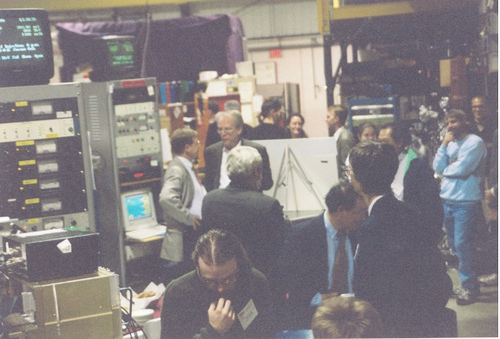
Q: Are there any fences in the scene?
A: No, there are no fences.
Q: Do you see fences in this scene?
A: No, there are no fences.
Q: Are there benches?
A: No, there are no benches.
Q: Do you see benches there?
A: No, there are no benches.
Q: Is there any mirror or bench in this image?
A: No, there are no benches or mirrors.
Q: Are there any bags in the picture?
A: No, there are no bags.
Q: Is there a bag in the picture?
A: No, there are no bags.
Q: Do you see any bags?
A: No, there are no bags.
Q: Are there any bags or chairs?
A: No, there are no bags or chairs.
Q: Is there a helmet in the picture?
A: No, there are no helmets.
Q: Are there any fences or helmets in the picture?
A: No, there are no helmets or fences.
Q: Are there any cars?
A: No, there are no cars.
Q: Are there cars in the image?
A: No, there are no cars.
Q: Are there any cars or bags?
A: No, there are no cars or bags.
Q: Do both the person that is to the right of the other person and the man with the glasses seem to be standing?
A: Yes, both the person and the man are standing.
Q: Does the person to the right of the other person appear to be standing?
A: Yes, the person is standing.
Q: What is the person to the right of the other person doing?
A: The person is standing.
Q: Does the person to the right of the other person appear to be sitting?
A: No, the person is standing.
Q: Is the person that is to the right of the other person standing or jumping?
A: The person is standing.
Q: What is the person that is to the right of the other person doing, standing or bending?
A: The person is standing.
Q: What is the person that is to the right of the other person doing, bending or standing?
A: The person is standing.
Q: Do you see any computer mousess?
A: No, there are no computer mousess.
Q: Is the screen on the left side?
A: Yes, the screen is on the left of the image.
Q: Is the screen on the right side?
A: No, the screen is on the left of the image.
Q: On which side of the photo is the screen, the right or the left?
A: The screen is on the left of the image.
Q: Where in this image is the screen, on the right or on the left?
A: The screen is on the left of the image.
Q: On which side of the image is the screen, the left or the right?
A: The screen is on the left of the image.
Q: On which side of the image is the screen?
A: The screen is on the left of the image.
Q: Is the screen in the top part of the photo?
A: Yes, the screen is in the top of the image.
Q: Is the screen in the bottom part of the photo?
A: No, the screen is in the top of the image.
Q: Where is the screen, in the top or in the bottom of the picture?
A: The screen is in the top of the image.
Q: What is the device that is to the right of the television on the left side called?
A: The device is a screen.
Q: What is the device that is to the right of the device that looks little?
A: The device is a screen.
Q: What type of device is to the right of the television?
A: The device is a screen.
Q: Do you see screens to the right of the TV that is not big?
A: Yes, there is a screen to the right of the television.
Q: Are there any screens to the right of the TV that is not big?
A: Yes, there is a screen to the right of the television.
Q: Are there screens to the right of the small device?
A: Yes, there is a screen to the right of the television.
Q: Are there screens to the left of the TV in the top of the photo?
A: No, the screen is to the right of the television.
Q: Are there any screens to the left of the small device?
A: No, the screen is to the right of the television.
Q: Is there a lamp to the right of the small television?
A: No, there is a screen to the right of the TV.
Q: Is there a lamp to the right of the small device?
A: No, there is a screen to the right of the TV.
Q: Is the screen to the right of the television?
A: Yes, the screen is to the right of the television.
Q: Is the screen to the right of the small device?
A: Yes, the screen is to the right of the television.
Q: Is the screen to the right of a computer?
A: No, the screen is to the right of the television.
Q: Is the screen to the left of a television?
A: No, the screen is to the right of a television.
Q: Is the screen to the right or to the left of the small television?
A: The screen is to the right of the television.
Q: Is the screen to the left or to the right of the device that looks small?
A: The screen is to the right of the television.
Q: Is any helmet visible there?
A: No, there are no helmets.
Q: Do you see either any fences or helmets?
A: No, there are no helmets or fences.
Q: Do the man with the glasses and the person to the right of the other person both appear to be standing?
A: Yes, both the man and the person are standing.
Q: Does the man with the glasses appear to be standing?
A: Yes, the man is standing.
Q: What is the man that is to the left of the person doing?
A: The man is standing.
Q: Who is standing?
A: The man is standing.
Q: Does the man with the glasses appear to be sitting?
A: No, the man is standing.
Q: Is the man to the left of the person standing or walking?
A: The man is standing.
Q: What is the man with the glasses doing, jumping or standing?
A: The man is standing.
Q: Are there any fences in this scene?
A: No, there are no fences.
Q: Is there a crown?
A: No, there are no crowns.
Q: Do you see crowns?
A: No, there are no crowns.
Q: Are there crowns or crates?
A: No, there are no crowns or crates.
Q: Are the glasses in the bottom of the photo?
A: Yes, the glasses are in the bottom of the image.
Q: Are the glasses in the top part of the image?
A: No, the glasses are in the bottom of the image.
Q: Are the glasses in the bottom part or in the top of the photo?
A: The glasses are in the bottom of the image.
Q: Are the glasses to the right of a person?
A: No, the glasses are to the left of a person.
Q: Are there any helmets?
A: No, there are no helmets.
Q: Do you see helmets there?
A: No, there are no helmets.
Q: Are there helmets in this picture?
A: No, there are no helmets.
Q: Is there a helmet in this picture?
A: No, there are no helmets.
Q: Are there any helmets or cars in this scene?
A: No, there are no helmets or cars.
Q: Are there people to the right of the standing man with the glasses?
A: Yes, there is a person to the right of the man.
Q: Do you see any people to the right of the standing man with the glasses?
A: Yes, there is a person to the right of the man.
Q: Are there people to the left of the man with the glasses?
A: No, the person is to the right of the man.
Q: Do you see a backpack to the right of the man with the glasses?
A: No, there is a person to the right of the man.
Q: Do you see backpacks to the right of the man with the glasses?
A: No, there is a person to the right of the man.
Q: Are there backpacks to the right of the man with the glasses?
A: No, there is a person to the right of the man.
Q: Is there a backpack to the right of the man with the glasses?
A: No, there is a person to the right of the man.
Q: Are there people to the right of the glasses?
A: Yes, there is a person to the right of the glasses.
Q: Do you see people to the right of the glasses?
A: Yes, there is a person to the right of the glasses.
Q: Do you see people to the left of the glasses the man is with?
A: No, the person is to the right of the glasses.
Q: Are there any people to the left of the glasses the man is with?
A: No, the person is to the right of the glasses.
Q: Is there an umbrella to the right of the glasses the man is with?
A: No, there is a person to the right of the glasses.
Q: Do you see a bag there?
A: No, there are no bags.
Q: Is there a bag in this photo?
A: No, there are no bags.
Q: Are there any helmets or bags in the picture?
A: No, there are no bags or helmets.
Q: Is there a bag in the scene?
A: No, there are no bags.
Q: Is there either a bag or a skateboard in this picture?
A: No, there are no bags or skateboards.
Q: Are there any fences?
A: No, there are no fences.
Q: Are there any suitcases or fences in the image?
A: No, there are no fences or suitcases.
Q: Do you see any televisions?
A: Yes, there is a television.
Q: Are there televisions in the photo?
A: Yes, there is a television.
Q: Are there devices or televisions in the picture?
A: Yes, there is a television.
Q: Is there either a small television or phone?
A: Yes, there is a small television.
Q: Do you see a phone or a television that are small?
A: Yes, the television is small.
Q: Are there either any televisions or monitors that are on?
A: Yes, the television is on.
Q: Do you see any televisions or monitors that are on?
A: Yes, the television is on.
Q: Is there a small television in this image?
A: Yes, there is a small television.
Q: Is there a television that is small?
A: Yes, there is a television that is small.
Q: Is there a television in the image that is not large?
A: Yes, there is a small television.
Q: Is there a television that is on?
A: Yes, there is a television that is on.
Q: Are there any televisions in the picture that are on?
A: Yes, there is a television that is on.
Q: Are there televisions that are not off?
A: Yes, there is a television that is on.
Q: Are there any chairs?
A: No, there are no chairs.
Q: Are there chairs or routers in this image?
A: No, there are no chairs or routers.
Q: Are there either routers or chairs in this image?
A: No, there are no chairs or routers.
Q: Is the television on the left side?
A: Yes, the television is on the left of the image.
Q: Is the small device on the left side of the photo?
A: Yes, the television is on the left of the image.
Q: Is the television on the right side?
A: No, the television is on the left of the image.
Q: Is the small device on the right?
A: No, the television is on the left of the image.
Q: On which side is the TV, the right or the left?
A: The TV is on the left of the image.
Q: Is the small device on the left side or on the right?
A: The TV is on the left of the image.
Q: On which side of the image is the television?
A: The television is on the left of the image.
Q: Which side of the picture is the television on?
A: The television is on the left of the image.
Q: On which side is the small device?
A: The television is on the left of the image.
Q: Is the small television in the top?
A: Yes, the television is in the top of the image.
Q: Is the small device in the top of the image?
A: Yes, the television is in the top of the image.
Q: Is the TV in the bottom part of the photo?
A: No, the TV is in the top of the image.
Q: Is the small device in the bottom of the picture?
A: No, the TV is in the top of the image.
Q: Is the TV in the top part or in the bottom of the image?
A: The TV is in the top of the image.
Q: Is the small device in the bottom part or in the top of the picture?
A: The TV is in the top of the image.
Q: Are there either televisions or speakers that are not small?
A: No, there is a television but it is small.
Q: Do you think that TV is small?
A: Yes, the TV is small.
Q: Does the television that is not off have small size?
A: Yes, the TV is small.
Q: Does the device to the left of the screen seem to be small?
A: Yes, the TV is small.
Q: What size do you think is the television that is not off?
A: The TV is small.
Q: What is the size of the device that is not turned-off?
A: The TV is small.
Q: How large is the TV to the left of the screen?
A: The television is small.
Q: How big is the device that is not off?
A: The television is small.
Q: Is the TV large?
A: No, the TV is small.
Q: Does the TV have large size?
A: No, the TV is small.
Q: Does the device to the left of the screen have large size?
A: No, the TV is small.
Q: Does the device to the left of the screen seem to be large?
A: No, the TV is small.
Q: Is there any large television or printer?
A: No, there is a television but it is small.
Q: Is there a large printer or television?
A: No, there is a television but it is small.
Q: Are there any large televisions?
A: No, there is a television but it is small.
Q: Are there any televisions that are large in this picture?
A: No, there is a television but it is small.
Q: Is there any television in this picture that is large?
A: No, there is a television but it is small.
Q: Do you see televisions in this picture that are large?
A: No, there is a television but it is small.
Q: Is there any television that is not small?
A: No, there is a television but it is small.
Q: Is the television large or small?
A: The television is small.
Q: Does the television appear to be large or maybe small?
A: The television is small.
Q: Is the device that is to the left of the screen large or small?
A: The television is small.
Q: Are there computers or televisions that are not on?
A: No, there is a television but it is on.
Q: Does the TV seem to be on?
A: Yes, the TV is on.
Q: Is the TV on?
A: Yes, the TV is on.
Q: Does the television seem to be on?
A: Yes, the television is on.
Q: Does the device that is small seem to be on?
A: Yes, the television is on.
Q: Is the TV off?
A: No, the TV is on.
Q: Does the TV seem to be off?
A: No, the TV is on.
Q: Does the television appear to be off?
A: No, the television is on.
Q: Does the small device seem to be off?
A: No, the television is on.